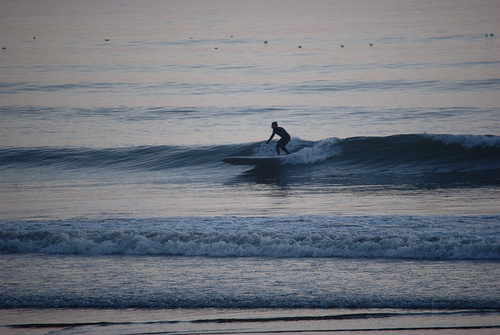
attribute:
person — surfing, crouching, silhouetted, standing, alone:
[268, 120, 289, 156]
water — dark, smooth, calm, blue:
[0, 0, 499, 309]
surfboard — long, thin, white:
[223, 156, 290, 167]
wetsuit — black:
[270, 129, 290, 152]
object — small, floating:
[299, 45, 305, 48]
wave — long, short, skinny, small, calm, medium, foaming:
[0, 135, 499, 176]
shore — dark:
[0, 306, 499, 332]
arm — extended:
[267, 131, 278, 143]